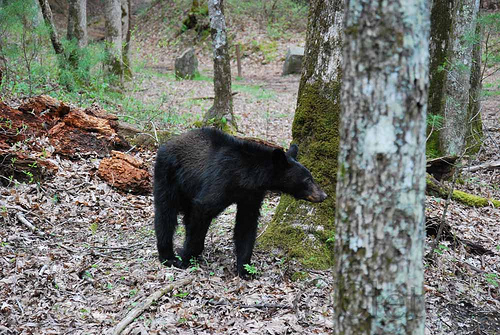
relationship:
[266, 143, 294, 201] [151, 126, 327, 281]
neck of animal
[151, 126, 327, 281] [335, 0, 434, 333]
animal standing by tree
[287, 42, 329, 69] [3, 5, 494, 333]
rock on ground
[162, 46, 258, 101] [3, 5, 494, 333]
rock on ground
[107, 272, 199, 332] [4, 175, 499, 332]
debris lying on ground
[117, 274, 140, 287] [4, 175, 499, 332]
debris lying on ground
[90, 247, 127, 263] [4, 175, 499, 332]
debris lying on ground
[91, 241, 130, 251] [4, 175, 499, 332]
debris lying on ground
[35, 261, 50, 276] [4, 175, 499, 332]
debris lying on ground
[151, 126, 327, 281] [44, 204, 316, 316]
animal on leaves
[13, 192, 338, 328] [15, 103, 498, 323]
leaves on ground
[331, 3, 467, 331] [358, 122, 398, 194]
tree has bark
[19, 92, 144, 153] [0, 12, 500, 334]
wooden on leaves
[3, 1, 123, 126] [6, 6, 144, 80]
plants near wood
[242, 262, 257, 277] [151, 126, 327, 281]
plant near animal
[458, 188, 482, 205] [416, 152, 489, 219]
plant on log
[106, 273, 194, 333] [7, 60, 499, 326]
stick on ground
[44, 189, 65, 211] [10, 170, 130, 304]
twig on ground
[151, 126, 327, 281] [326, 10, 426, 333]
animal looking right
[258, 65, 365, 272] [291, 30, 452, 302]
moss on tree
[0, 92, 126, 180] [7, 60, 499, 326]
wood on ground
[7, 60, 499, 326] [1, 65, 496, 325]
ground made of dirt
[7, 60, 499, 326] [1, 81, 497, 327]
ground made of branches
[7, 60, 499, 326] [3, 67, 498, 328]
ground made of trees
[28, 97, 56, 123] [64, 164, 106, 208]
wood on ground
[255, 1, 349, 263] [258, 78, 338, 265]
trunk covered in moss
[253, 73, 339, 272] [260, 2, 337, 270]
lichens growing in tree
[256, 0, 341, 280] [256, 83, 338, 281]
plant with moss